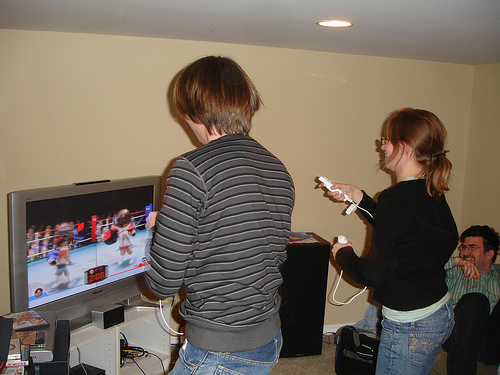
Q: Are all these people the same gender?
A: No, they are both male and female.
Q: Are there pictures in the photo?
A: No, there are no pictures.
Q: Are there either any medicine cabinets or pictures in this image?
A: No, there are no pictures or medicine cabinets.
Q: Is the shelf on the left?
A: Yes, the shelf is on the left of the image.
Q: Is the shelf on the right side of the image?
A: No, the shelf is on the left of the image.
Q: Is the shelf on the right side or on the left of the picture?
A: The shelf is on the left of the image.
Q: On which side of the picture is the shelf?
A: The shelf is on the left of the image.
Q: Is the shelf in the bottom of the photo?
A: Yes, the shelf is in the bottom of the image.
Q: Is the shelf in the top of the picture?
A: No, the shelf is in the bottom of the image.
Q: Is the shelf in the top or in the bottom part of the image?
A: The shelf is in the bottom of the image.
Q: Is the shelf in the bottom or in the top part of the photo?
A: The shelf is in the bottom of the image.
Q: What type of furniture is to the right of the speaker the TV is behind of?
A: The piece of furniture is a shelf.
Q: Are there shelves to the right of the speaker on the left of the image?
A: Yes, there is a shelf to the right of the speaker.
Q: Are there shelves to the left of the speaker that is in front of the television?
A: No, the shelf is to the right of the speaker.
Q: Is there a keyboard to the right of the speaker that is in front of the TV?
A: No, there is a shelf to the right of the speaker.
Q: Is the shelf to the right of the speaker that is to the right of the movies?
A: Yes, the shelf is to the right of the speaker.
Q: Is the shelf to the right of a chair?
A: No, the shelf is to the right of the speaker.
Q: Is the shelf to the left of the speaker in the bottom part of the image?
A: No, the shelf is to the right of the speaker.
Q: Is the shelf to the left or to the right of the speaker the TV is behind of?
A: The shelf is to the right of the speaker.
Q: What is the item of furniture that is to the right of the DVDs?
A: The piece of furniture is a shelf.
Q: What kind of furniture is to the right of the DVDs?
A: The piece of furniture is a shelf.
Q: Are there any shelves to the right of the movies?
A: Yes, there is a shelf to the right of the movies.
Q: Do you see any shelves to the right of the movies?
A: Yes, there is a shelf to the right of the movies.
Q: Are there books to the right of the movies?
A: No, there is a shelf to the right of the movies.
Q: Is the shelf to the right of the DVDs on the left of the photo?
A: Yes, the shelf is to the right of the DVDs.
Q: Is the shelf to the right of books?
A: No, the shelf is to the right of the DVDs.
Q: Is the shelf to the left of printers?
A: No, the shelf is to the left of the speakers.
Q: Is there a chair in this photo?
A: No, there are no chairs.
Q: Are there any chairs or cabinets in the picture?
A: No, there are no chairs or cabinets.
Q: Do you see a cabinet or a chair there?
A: No, there are no chairs or cabinets.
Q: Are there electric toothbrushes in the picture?
A: No, there are no electric toothbrushes.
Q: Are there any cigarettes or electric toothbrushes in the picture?
A: No, there are no electric toothbrushes or cigarettes.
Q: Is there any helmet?
A: No, there are no helmets.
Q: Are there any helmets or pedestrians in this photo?
A: No, there are no helmets or pedestrians.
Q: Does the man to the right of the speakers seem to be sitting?
A: Yes, the man is sitting.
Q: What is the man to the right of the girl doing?
A: The man is sitting.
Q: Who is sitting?
A: The man is sitting.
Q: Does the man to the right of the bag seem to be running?
A: No, the man is sitting.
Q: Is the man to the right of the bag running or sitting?
A: The man is sitting.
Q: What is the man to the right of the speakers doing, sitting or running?
A: The man is sitting.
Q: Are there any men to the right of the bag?
A: Yes, there is a man to the right of the bag.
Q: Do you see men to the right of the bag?
A: Yes, there is a man to the right of the bag.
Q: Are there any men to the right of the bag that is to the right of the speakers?
A: Yes, there is a man to the right of the bag.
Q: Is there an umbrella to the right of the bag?
A: No, there is a man to the right of the bag.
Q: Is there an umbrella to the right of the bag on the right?
A: No, there is a man to the right of the bag.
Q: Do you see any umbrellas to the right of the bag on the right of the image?
A: No, there is a man to the right of the bag.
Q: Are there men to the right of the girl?
A: Yes, there is a man to the right of the girl.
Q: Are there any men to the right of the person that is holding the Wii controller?
A: Yes, there is a man to the right of the girl.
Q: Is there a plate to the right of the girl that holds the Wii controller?
A: No, there is a man to the right of the girl.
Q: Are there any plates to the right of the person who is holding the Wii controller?
A: No, there is a man to the right of the girl.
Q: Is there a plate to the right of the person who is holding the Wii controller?
A: No, there is a man to the right of the girl.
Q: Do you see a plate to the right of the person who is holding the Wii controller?
A: No, there is a man to the right of the girl.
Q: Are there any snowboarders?
A: No, there are no snowboarders.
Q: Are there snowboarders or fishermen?
A: No, there are no snowboarders or fishermen.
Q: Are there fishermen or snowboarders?
A: No, there are no snowboarders or fishermen.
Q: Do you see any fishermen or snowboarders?
A: No, there are no snowboarders or fishermen.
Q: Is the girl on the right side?
A: Yes, the girl is on the right of the image.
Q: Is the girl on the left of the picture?
A: No, the girl is on the right of the image.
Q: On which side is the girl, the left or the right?
A: The girl is on the right of the image.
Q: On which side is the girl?
A: The girl is on the right of the image.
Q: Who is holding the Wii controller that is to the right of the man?
A: The girl is holding the Wii remotes.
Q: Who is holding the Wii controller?
A: The girl is holding the Wii remotes.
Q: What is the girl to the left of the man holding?
A: The girl is holding the Wii remotes.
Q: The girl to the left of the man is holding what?
A: The girl is holding the Wii remotes.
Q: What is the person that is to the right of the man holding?
A: The girl is holding the Wii remotes.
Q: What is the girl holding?
A: The girl is holding the Wii remotes.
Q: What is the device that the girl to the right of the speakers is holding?
A: The device is a Wii controller.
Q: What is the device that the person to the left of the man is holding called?
A: The device is a Wii controller.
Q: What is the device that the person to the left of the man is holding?
A: The device is a Wii controller.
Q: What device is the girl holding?
A: The girl is holding the Wii controller.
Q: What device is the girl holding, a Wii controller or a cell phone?
A: The girl is holding a Wii controller.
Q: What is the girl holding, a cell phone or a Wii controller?
A: The girl is holding a Wii controller.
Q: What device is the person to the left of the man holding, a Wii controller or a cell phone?
A: The girl is holding a Wii controller.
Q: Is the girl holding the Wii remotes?
A: Yes, the girl is holding the Wii remotes.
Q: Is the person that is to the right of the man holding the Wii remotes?
A: Yes, the girl is holding the Wii remotes.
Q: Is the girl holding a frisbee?
A: No, the girl is holding the Wii remotes.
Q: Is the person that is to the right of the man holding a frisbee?
A: No, the girl is holding the Wii remotes.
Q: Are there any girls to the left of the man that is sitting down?
A: Yes, there is a girl to the left of the man.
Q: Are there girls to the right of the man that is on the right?
A: No, the girl is to the left of the man.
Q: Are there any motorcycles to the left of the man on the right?
A: No, there is a girl to the left of the man.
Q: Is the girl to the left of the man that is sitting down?
A: Yes, the girl is to the left of the man.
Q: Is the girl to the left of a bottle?
A: No, the girl is to the left of the man.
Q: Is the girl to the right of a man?
A: No, the girl is to the left of a man.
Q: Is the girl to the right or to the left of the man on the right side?
A: The girl is to the left of the man.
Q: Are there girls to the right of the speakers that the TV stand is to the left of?
A: Yes, there is a girl to the right of the speakers.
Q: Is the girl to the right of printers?
A: No, the girl is to the right of the speakers.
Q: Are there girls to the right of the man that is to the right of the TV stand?
A: Yes, there is a girl to the right of the man.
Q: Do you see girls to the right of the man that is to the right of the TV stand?
A: Yes, there is a girl to the right of the man.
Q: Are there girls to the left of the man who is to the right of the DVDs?
A: No, the girl is to the right of the man.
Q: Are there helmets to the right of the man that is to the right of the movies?
A: No, there is a girl to the right of the man.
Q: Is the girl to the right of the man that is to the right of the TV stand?
A: Yes, the girl is to the right of the man.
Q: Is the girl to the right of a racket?
A: No, the girl is to the right of the man.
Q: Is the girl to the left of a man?
A: No, the girl is to the right of a man.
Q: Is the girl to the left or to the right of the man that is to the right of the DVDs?
A: The girl is to the right of the man.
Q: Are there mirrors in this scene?
A: No, there are no mirrors.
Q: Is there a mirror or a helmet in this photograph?
A: No, there are no mirrors or helmets.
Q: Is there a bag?
A: Yes, there is a bag.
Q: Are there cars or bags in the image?
A: Yes, there is a bag.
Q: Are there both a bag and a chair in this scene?
A: No, there is a bag but no chairs.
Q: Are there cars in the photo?
A: No, there are no cars.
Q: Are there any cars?
A: No, there are no cars.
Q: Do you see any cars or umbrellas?
A: No, there are no cars or umbrellas.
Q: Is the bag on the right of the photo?
A: Yes, the bag is on the right of the image.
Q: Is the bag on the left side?
A: No, the bag is on the right of the image.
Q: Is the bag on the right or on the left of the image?
A: The bag is on the right of the image.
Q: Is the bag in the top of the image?
A: No, the bag is in the bottom of the image.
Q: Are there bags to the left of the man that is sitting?
A: Yes, there is a bag to the left of the man.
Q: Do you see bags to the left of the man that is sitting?
A: Yes, there is a bag to the left of the man.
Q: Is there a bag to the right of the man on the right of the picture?
A: No, the bag is to the left of the man.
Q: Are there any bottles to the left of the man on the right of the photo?
A: No, there is a bag to the left of the man.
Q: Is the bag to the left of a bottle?
A: No, the bag is to the left of a man.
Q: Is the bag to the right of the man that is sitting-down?
A: No, the bag is to the left of the man.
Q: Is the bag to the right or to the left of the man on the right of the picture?
A: The bag is to the left of the man.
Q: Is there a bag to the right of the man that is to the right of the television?
A: Yes, there is a bag to the right of the man.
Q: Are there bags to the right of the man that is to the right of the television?
A: Yes, there is a bag to the right of the man.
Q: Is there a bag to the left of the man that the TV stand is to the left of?
A: No, the bag is to the right of the man.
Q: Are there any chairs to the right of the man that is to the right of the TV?
A: No, there is a bag to the right of the man.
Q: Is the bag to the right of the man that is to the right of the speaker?
A: Yes, the bag is to the right of the man.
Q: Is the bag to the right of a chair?
A: No, the bag is to the right of the man.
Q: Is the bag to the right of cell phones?
A: No, the bag is to the right of the speakers.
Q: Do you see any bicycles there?
A: No, there are no bicycles.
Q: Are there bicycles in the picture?
A: No, there are no bicycles.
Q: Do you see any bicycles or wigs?
A: No, there are no bicycles or wigs.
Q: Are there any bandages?
A: No, there are no bandages.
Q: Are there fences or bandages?
A: No, there are no bandages or fences.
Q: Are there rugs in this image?
A: No, there are no rugs.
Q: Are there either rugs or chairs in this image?
A: No, there are no rugs or chairs.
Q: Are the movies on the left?
A: Yes, the movies are on the left of the image.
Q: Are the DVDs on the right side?
A: No, the DVDs are on the left of the image.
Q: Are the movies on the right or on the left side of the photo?
A: The movies are on the left of the image.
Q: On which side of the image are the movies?
A: The movies are on the left of the image.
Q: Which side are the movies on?
A: The movies are on the left of the image.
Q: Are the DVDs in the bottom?
A: Yes, the DVDs are in the bottom of the image.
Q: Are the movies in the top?
A: No, the movies are in the bottom of the image.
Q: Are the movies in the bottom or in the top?
A: The movies are in the bottom of the image.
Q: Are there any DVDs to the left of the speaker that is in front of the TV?
A: Yes, there are DVDs to the left of the speaker.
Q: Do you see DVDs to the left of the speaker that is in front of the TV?
A: Yes, there are DVDs to the left of the speaker.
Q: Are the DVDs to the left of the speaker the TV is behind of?
A: Yes, the DVDs are to the left of the speaker.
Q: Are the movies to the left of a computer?
A: No, the movies are to the left of the speaker.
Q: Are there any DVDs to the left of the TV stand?
A: Yes, there are DVDs to the left of the TV stand.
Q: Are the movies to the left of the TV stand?
A: Yes, the movies are to the left of the TV stand.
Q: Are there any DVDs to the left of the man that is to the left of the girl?
A: Yes, there are DVDs to the left of the man.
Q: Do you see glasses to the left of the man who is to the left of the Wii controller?
A: No, there are DVDs to the left of the man.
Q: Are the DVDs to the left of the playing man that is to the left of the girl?
A: Yes, the DVDs are to the left of the man.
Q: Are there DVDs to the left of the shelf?
A: Yes, there are DVDs to the left of the shelf.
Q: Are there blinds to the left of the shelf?
A: No, there are DVDs to the left of the shelf.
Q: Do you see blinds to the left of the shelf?
A: No, there are DVDs to the left of the shelf.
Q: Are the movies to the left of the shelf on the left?
A: Yes, the movies are to the left of the shelf.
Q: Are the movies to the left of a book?
A: No, the movies are to the left of the shelf.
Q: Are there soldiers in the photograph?
A: No, there are no soldiers.